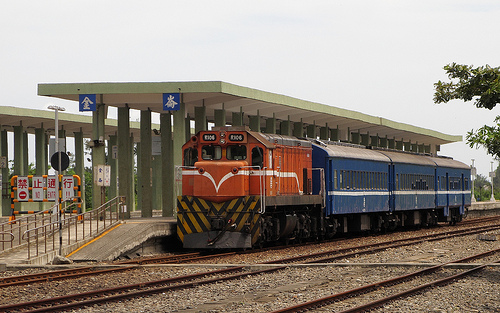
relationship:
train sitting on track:
[179, 130, 473, 248] [268, 248, 498, 311]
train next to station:
[179, 130, 473, 248] [38, 80, 464, 269]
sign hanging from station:
[162, 89, 181, 110] [38, 80, 464, 269]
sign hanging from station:
[75, 94, 98, 111] [38, 80, 464, 269]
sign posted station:
[162, 89, 181, 110] [38, 80, 464, 269]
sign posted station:
[75, 94, 98, 111] [38, 80, 464, 269]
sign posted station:
[94, 161, 115, 188] [38, 80, 464, 269]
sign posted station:
[8, 173, 83, 205] [38, 80, 464, 269]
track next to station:
[268, 248, 498, 311] [38, 80, 464, 269]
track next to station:
[7, 223, 499, 313] [38, 80, 464, 269]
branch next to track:
[436, 63, 498, 110] [268, 248, 498, 311]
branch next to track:
[464, 117, 498, 159] [268, 248, 498, 311]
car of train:
[305, 138, 390, 216] [179, 130, 473, 248]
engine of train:
[180, 131, 311, 214] [179, 130, 473, 248]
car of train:
[376, 146, 434, 214] [179, 130, 473, 248]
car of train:
[425, 153, 468, 205] [179, 130, 473, 248]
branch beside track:
[436, 63, 498, 110] [268, 248, 498, 311]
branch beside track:
[464, 117, 498, 159] [268, 248, 498, 311]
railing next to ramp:
[18, 196, 117, 258] [1, 215, 122, 266]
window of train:
[199, 145, 227, 162] [179, 130, 473, 248]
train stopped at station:
[179, 130, 473, 248] [38, 80, 464, 269]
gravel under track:
[2, 214, 497, 300] [268, 248, 498, 311]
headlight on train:
[198, 167, 206, 177] [179, 130, 473, 248]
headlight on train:
[229, 163, 240, 172] [179, 130, 473, 248]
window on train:
[199, 145, 227, 162] [179, 130, 473, 248]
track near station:
[268, 248, 498, 311] [38, 80, 464, 269]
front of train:
[180, 131, 311, 214] [179, 130, 473, 248]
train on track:
[179, 130, 473, 248] [268, 248, 498, 311]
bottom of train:
[177, 196, 475, 231] [179, 130, 473, 248]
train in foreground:
[179, 130, 473, 248] [15, 227, 488, 311]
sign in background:
[162, 89, 181, 110] [1, 38, 498, 138]